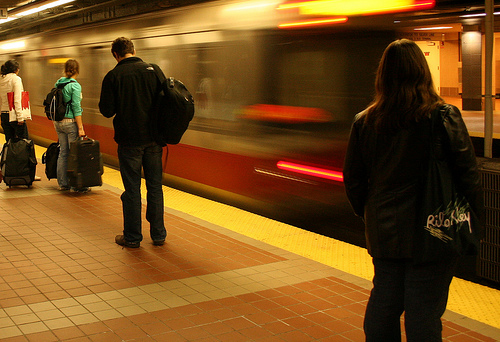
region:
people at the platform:
[6, 43, 482, 328]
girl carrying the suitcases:
[32, 51, 109, 211]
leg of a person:
[359, 238, 420, 328]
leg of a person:
[395, 242, 469, 318]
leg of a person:
[117, 167, 145, 220]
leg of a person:
[149, 157, 181, 225]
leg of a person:
[66, 129, 95, 171]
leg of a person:
[55, 141, 73, 173]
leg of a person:
[15, 118, 40, 145]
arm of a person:
[89, 75, 112, 120]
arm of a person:
[62, 98, 96, 136]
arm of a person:
[0, 85, 31, 112]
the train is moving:
[5, 6, 499, 258]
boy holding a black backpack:
[91, 28, 205, 260]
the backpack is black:
[130, 58, 197, 154]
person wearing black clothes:
[95, 28, 204, 250]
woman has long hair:
[322, 21, 489, 203]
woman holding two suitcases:
[37, 50, 109, 201]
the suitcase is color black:
[61, 130, 106, 192]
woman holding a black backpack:
[36, 54, 93, 137]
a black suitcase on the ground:
[1, 131, 44, 191]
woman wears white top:
[1, 58, 37, 132]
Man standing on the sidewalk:
[77, 28, 216, 254]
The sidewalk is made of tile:
[217, 236, 336, 331]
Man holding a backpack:
[127, 48, 201, 143]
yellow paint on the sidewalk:
[243, 213, 350, 266]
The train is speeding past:
[210, 25, 322, 154]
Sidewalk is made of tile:
[44, 249, 154, 339]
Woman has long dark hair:
[366, 38, 476, 102]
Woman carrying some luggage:
[34, 117, 108, 177]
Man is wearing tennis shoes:
[100, 227, 139, 256]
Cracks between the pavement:
[72, 269, 105, 288]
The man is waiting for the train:
[87, 25, 211, 267]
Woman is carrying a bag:
[412, 133, 495, 250]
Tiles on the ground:
[150, 255, 301, 337]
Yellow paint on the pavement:
[255, 218, 362, 294]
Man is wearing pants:
[100, 126, 174, 251]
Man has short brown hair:
[107, 26, 146, 62]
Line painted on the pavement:
[112, 265, 198, 340]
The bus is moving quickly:
[235, 51, 330, 158]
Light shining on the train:
[460, 4, 487, 42]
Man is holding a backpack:
[124, 48, 222, 163]